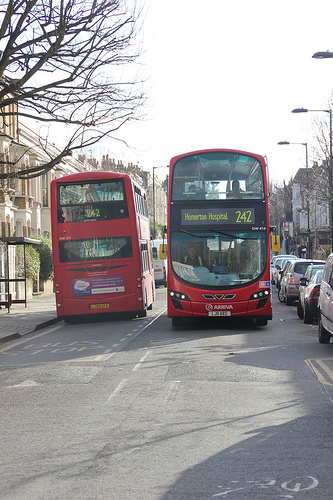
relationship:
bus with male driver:
[152, 136, 279, 318] [174, 235, 212, 272]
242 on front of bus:
[233, 208, 253, 225] [166, 147, 271, 328]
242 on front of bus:
[87, 209, 99, 217] [46, 170, 155, 324]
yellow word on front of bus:
[206, 211, 229, 220] [166, 147, 271, 328]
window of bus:
[173, 153, 264, 196] [151, 119, 286, 344]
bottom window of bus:
[54, 235, 132, 261] [46, 170, 155, 324]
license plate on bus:
[203, 309, 230, 315] [150, 141, 286, 341]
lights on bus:
[166, 287, 193, 301] [41, 163, 168, 322]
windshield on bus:
[168, 230, 266, 287] [166, 147, 271, 328]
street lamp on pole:
[278, 140, 306, 145] [301, 138, 313, 255]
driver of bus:
[178, 237, 212, 288] [166, 147, 271, 328]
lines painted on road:
[107, 347, 151, 407] [7, 288, 320, 469]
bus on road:
[166, 147, 271, 328] [2, 288, 333, 499]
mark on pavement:
[211, 469, 321, 498] [13, 277, 322, 497]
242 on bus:
[233, 208, 253, 225] [166, 147, 271, 328]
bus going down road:
[46, 170, 155, 324] [2, 288, 333, 499]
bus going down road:
[166, 147, 271, 328] [2, 288, 333, 499]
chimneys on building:
[81, 150, 152, 177] [1, 81, 161, 321]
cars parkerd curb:
[279, 221, 332, 352] [17, 303, 79, 363]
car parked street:
[270, 255, 289, 285] [130, 344, 270, 454]